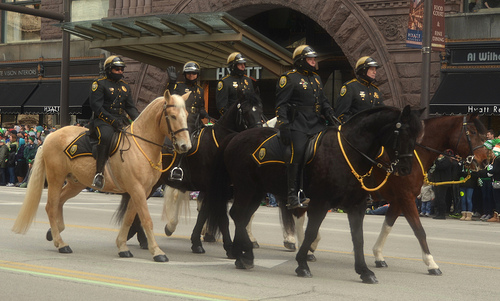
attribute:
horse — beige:
[52, 135, 150, 237]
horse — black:
[230, 148, 274, 180]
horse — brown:
[433, 120, 474, 140]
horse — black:
[198, 133, 213, 154]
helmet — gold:
[360, 57, 367, 61]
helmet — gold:
[296, 50, 302, 54]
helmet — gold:
[230, 55, 233, 59]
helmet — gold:
[105, 57, 111, 64]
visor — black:
[308, 54, 319, 58]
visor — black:
[371, 63, 380, 68]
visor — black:
[240, 62, 246, 66]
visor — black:
[187, 70, 197, 75]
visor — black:
[117, 65, 127, 72]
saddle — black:
[78, 137, 87, 155]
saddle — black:
[272, 145, 281, 153]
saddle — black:
[192, 135, 199, 142]